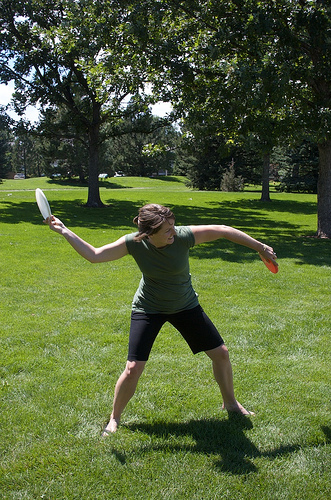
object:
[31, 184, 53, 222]
frisbee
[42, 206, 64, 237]
hand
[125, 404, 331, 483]
shadow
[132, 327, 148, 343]
black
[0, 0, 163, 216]
tree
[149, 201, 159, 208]
light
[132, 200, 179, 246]
hair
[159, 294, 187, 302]
green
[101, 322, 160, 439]
legs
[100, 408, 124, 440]
feet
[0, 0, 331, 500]
park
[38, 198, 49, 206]
white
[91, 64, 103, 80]
green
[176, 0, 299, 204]
trees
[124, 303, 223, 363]
shorts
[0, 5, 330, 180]
background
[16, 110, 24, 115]
leaf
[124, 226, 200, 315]
shirt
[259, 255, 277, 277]
red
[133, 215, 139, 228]
ponytail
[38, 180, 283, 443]
woman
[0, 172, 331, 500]
grass